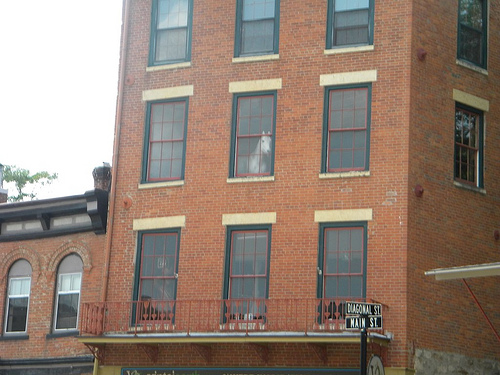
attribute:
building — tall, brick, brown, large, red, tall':
[94, 1, 499, 374]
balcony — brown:
[80, 301, 389, 346]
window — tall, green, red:
[230, 90, 282, 182]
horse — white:
[239, 131, 272, 173]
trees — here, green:
[1, 164, 58, 201]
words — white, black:
[347, 303, 383, 329]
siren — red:
[418, 48, 427, 63]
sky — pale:
[4, 0, 126, 192]